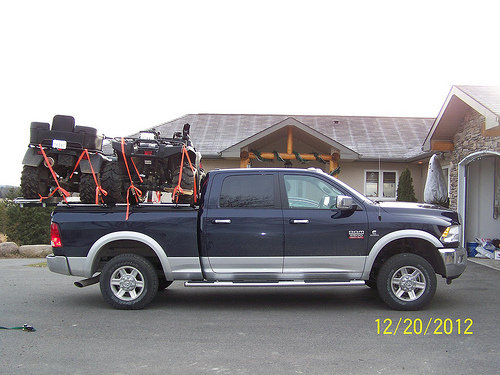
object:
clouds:
[1, 0, 500, 133]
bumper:
[440, 243, 469, 284]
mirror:
[337, 194, 354, 211]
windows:
[361, 167, 408, 208]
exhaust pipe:
[74, 274, 101, 289]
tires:
[98, 254, 160, 311]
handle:
[292, 219, 308, 223]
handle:
[213, 219, 232, 224]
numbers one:
[375, 317, 382, 334]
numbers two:
[382, 318, 392, 334]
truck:
[45, 151, 463, 311]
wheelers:
[18, 113, 96, 200]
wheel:
[372, 250, 439, 311]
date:
[376, 315, 474, 336]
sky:
[0, 0, 500, 166]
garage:
[448, 148, 497, 267]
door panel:
[282, 174, 368, 275]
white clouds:
[2, 0, 500, 108]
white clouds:
[0, 0, 500, 141]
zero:
[443, 318, 453, 335]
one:
[456, 319, 462, 334]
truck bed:
[44, 200, 201, 286]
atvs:
[100, 123, 199, 204]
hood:
[376, 200, 457, 215]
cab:
[203, 168, 365, 285]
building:
[119, 82, 498, 270]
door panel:
[206, 170, 286, 274]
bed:
[46, 202, 206, 280]